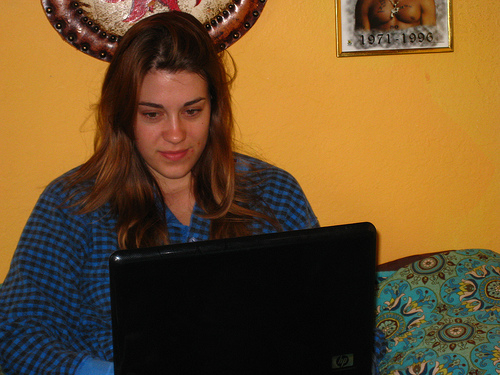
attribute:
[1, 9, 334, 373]
girl — sitting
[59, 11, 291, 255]
hair — long, brown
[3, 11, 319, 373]
woman — young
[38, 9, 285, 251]
hair — long, brown, straight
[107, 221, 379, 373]
computer — black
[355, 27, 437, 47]
dates —  1971-1990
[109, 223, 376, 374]
laptop — black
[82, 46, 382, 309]
using laptop —  woman's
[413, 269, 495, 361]
cover — aqua, brown, red, yellow, flowered, circled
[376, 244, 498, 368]
upholstery pattern — paisley, floral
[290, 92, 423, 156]
wall. — orange, painted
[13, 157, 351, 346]
shirt — blue, black, plaid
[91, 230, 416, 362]
laptop — black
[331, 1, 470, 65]
frame — gold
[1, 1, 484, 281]
wall — yellow, painted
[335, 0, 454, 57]
picture —  for memorial